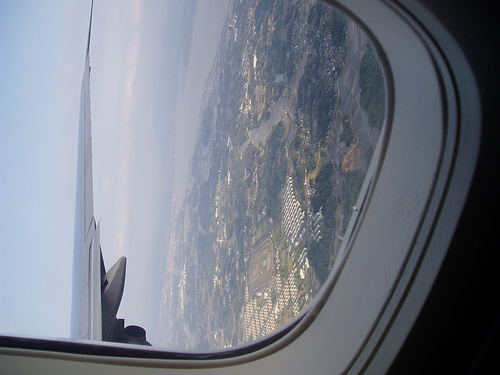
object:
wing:
[70, 0, 103, 340]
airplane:
[0, 0, 499, 375]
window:
[0, 1, 395, 353]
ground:
[237, 266, 306, 348]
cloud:
[114, 3, 143, 77]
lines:
[345, 158, 472, 374]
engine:
[100, 248, 154, 346]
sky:
[1, 0, 228, 346]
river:
[233, 81, 303, 157]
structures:
[207, 220, 238, 290]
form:
[243, 231, 278, 296]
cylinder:
[124, 324, 148, 341]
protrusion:
[99, 247, 127, 319]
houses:
[307, 207, 326, 246]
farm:
[202, 298, 214, 321]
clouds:
[116, 165, 169, 227]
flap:
[88, 218, 102, 341]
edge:
[322, 56, 478, 374]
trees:
[257, 119, 286, 223]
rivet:
[349, 204, 359, 212]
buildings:
[280, 177, 309, 250]